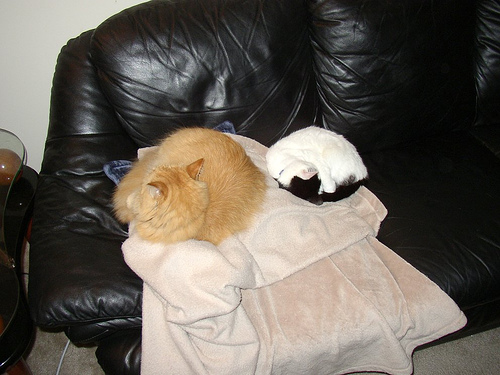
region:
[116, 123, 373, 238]
Two cats on a blanket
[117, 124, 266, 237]
Brown cat on blanket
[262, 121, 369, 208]
white and black cat on blanket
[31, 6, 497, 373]
two cats on black leather couch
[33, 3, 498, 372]
Black leather couch against white wall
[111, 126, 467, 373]
tan blanket on black couch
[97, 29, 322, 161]
Wrinkles on black couch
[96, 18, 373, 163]
Wrinkles on black leather couch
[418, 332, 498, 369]
gray carpet on floor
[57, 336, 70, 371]
Telephone card on floor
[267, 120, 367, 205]
black cat with white cover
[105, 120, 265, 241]
orange cat curled in ball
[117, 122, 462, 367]
pink blanket under cats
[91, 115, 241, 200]
blue jeans under pink blanket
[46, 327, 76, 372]
gray wire on carpet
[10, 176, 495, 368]
gray carpet under couch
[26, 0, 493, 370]
black leather sofa under blanket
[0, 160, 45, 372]
guitar next to sofa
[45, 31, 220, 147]
light reflecting on black sofa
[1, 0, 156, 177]
white wall behind sofa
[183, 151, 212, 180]
the ear of a cat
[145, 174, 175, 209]
the ear of a cat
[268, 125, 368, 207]
a cat sleeping on a pillow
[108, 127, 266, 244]
a cat sleeping on a pillow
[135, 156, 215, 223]
a head of a cat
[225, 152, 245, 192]
the fur of a cat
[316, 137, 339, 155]
the fur of a cat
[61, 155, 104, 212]
black leather of a chair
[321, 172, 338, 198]
the paw of a cat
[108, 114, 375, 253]
two cats sleeping on a pillow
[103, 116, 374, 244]
2 cats sleeping on blanket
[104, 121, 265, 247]
orange cat curled up in ball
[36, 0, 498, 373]
black leather sofa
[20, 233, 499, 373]
gray carpet under sofa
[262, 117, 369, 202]
black cat under white cover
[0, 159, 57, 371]
partial view of guitar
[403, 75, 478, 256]
the couch is black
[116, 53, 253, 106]
the couch is shiney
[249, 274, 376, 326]
the blanket is brown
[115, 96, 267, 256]
the cat is orange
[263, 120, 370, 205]
the cat is white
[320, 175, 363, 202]
the cat has a tail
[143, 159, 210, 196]
the cat has ears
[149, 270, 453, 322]
the blanket is on the couch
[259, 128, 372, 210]
the cat is on the blanket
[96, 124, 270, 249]
the cat is big